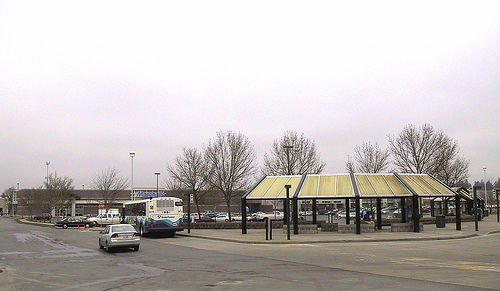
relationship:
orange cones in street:
[73, 222, 108, 229] [3, 213, 495, 288]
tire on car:
[59, 219, 69, 229] [54, 214, 96, 227]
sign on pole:
[187, 191, 198, 204] [189, 192, 194, 234]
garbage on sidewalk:
[433, 213, 448, 228] [217, 224, 485, 237]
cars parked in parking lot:
[54, 197, 184, 252] [53, 192, 465, 224]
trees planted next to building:
[28, 170, 66, 222] [7, 183, 286, 227]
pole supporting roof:
[235, 197, 253, 236] [239, 170, 460, 206]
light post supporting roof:
[42, 160, 56, 197] [239, 170, 460, 206]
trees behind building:
[15, 124, 500, 224] [222, 159, 481, 236]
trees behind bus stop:
[15, 124, 500, 224] [241, 172, 500, 239]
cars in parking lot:
[60, 204, 292, 229] [54, 206, 450, 226]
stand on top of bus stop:
[241, 172, 460, 201] [241, 171, 485, 233]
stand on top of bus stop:
[241, 172, 460, 201] [235, 172, 461, 237]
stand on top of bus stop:
[245, 172, 459, 202] [242, 167, 474, 237]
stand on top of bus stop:
[241, 172, 460, 201] [236, 175, 486, 237]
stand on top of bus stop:
[241, 172, 460, 201] [254, 199, 449, 227]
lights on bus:
[149, 198, 185, 238] [119, 197, 196, 241]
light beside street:
[149, 169, 163, 200] [147, 224, 238, 285]